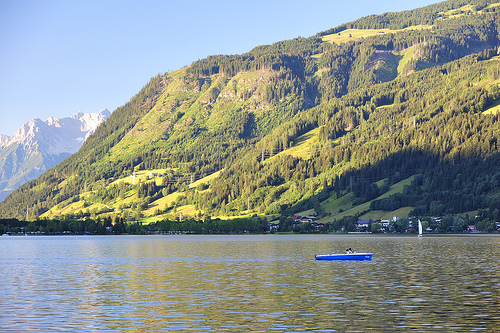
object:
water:
[2, 261, 499, 332]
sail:
[416, 219, 425, 235]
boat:
[417, 234, 423, 238]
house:
[357, 219, 371, 227]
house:
[379, 220, 390, 228]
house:
[292, 214, 318, 222]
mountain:
[229, 101, 500, 196]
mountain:
[132, 1, 500, 81]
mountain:
[0, 107, 113, 192]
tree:
[441, 214, 454, 230]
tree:
[394, 216, 409, 233]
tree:
[453, 218, 467, 232]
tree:
[476, 217, 490, 232]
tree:
[1, 222, 8, 234]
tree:
[26, 221, 37, 232]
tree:
[55, 221, 65, 233]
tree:
[87, 222, 97, 234]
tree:
[94, 222, 103, 234]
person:
[349, 247, 355, 253]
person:
[345, 249, 349, 255]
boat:
[315, 252, 374, 262]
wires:
[343, 126, 407, 143]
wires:
[260, 144, 350, 160]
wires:
[163, 174, 199, 184]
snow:
[63, 117, 88, 130]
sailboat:
[417, 218, 424, 238]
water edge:
[238, 232, 499, 248]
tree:
[342, 107, 357, 131]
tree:
[320, 120, 337, 140]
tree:
[280, 133, 289, 151]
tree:
[318, 110, 329, 126]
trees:
[277, 215, 314, 233]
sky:
[2, 1, 147, 78]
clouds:
[7, 6, 26, 26]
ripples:
[134, 290, 253, 327]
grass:
[127, 129, 157, 145]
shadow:
[414, 172, 499, 208]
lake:
[2, 234, 499, 332]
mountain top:
[23, 107, 111, 130]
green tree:
[357, 21, 363, 30]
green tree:
[376, 21, 381, 29]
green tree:
[389, 24, 395, 30]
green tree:
[355, 41, 363, 47]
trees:
[415, 9, 431, 16]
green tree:
[26, 222, 37, 234]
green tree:
[69, 221, 78, 234]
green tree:
[112, 222, 122, 234]